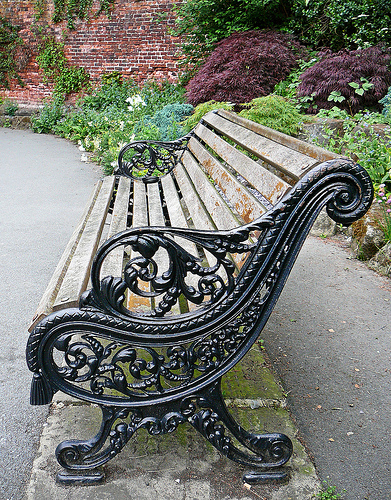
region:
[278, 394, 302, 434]
edge of a bench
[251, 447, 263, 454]
leg of a bench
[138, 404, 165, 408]
part of a bench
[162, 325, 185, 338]
arm of a bench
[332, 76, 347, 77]
section of purple leaves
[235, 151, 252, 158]
back of a bench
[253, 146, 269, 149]
back rest of a bench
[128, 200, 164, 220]
lower part of a bench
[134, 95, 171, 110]
section of a bushy plantation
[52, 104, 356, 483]
a wooden bench with ornate metal work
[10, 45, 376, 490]
a wooden bench in a garden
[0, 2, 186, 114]
a brick wall covered in ivy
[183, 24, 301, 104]
purple shrubbery grows in the background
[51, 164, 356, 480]
ornate craftsmanship on the armrest of bench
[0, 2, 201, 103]
a wall covered in vegetation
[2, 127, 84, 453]
a paved footpath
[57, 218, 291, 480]
floral patterns in cast iron portion of bench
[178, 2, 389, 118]
vegetation growing in the background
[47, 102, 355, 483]
bench has curving contours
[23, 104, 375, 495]
wood bench with wrought iron sides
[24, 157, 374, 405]
left wrought iron side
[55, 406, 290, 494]
left feet of bench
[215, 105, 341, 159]
top slat of bench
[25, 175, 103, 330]
bottom slat of bench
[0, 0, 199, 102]
brick wall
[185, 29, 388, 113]
two red japanese maples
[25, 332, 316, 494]
mossy concrete slab under bench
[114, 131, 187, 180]
far arm of bench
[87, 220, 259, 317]
near arm of bench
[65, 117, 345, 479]
A park bench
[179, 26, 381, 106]
A pair of purple bushes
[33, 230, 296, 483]
Iron detailed rails the bench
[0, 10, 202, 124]
A red brick wall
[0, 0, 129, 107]
Vines growing on the wall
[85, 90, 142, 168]
some white flowers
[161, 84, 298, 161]
a pair of green shrubs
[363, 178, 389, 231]
some pink flowers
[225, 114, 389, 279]
rocks outlining a natural area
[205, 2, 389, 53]
green trees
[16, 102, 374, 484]
a bench at the park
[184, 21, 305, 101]
a brown bushy flower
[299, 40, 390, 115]
a brown bushy flower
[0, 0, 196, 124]
a bricked wall on the background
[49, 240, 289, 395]
a floral pattern on the bench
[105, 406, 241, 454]
a floral pattern on the bench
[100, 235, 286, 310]
a floral pattern on the bench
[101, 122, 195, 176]
a floral pattern on the bench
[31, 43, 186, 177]
green plants on the ground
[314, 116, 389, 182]
green plants on the ground